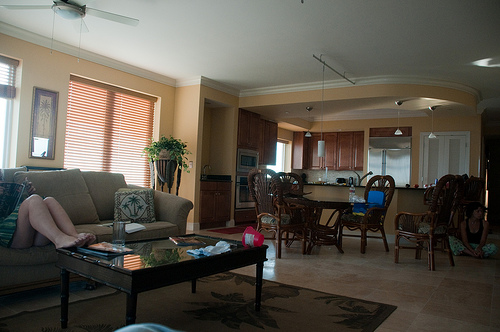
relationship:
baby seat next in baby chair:
[350, 187, 386, 217] [332, 173, 396, 255]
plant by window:
[141, 126, 203, 213] [65, 55, 174, 207]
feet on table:
[56, 231, 98, 251] [300, 186, 347, 208]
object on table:
[239, 222, 263, 249] [288, 190, 382, 255]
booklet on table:
[172, 237, 202, 244] [61, 233, 266, 322]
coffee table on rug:
[54, 232, 268, 328] [0, 268, 399, 330]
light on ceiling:
[426, 101, 440, 140] [242, 75, 482, 127]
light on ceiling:
[391, 97, 403, 134] [242, 75, 482, 127]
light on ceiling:
[303, 102, 317, 136] [242, 75, 482, 127]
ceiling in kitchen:
[242, 75, 482, 127] [230, 77, 490, 246]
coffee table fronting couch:
[54, 232, 270, 328] [0, 170, 194, 298]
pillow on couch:
[113, 183, 155, 221] [0, 170, 194, 298]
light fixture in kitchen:
[318, 64, 326, 157] [198, 114, 472, 244]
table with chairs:
[275, 196, 365, 253] [246, 167, 458, 271]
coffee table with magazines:
[54, 232, 268, 328] [80, 236, 135, 258]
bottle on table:
[341, 173, 371, 210] [282, 203, 393, 274]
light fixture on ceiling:
[314, 55, 329, 161] [234, 44, 470, 122]